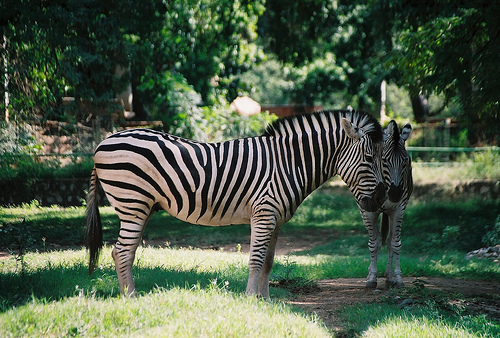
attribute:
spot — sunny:
[0, 276, 332, 336]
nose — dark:
[374, 196, 400, 218]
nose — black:
[372, 182, 385, 209]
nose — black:
[390, 183, 401, 201]